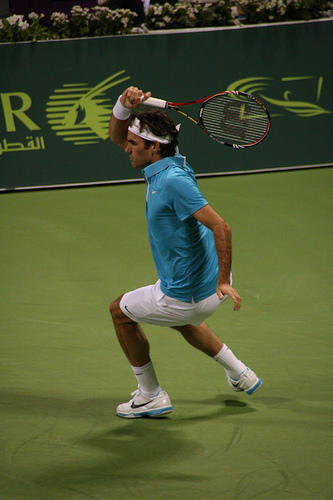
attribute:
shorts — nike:
[118, 277, 233, 326]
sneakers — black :
[120, 375, 264, 421]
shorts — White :
[117, 270, 232, 328]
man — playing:
[114, 113, 202, 208]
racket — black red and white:
[124, 77, 285, 157]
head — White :
[111, 108, 193, 178]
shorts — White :
[119, 279, 240, 337]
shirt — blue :
[138, 179, 206, 219]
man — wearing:
[81, 80, 282, 446]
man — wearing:
[105, 87, 264, 419]